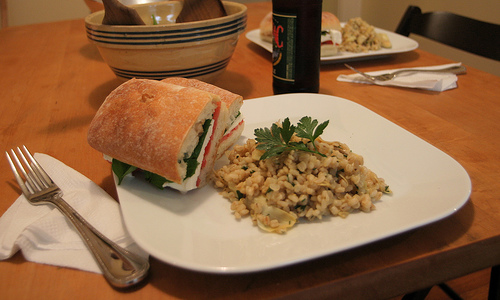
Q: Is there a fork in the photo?
A: Yes, there is a fork.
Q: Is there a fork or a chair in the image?
A: Yes, there is a fork.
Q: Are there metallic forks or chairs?
A: Yes, there is a metal fork.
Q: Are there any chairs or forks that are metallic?
A: Yes, the fork is metallic.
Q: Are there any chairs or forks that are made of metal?
A: Yes, the fork is made of metal.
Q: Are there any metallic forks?
A: Yes, there is a metal fork.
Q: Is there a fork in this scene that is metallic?
A: Yes, there is a fork that is metallic.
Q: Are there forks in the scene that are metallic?
A: Yes, there is a fork that is metallic.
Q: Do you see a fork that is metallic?
A: Yes, there is a fork that is metallic.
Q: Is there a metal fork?
A: Yes, there is a fork that is made of metal.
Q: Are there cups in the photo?
A: No, there are no cups.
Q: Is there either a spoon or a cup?
A: No, there are no cups or spoons.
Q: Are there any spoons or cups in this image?
A: No, there are no cups or spoons.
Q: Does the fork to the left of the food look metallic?
A: Yes, the fork is metallic.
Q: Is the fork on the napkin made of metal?
A: Yes, the fork is made of metal.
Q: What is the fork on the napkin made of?
A: The fork is made of metal.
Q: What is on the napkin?
A: The fork is on the napkin.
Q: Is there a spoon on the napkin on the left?
A: No, there is a fork on the napkin.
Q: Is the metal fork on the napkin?
A: Yes, the fork is on the napkin.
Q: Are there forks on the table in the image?
A: Yes, there is a fork on the table.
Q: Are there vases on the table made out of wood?
A: No, there is a fork on the table.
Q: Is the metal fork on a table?
A: Yes, the fork is on a table.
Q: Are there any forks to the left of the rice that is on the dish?
A: Yes, there is a fork to the left of the rice.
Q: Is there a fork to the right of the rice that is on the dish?
A: No, the fork is to the left of the rice.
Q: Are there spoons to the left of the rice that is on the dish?
A: No, there is a fork to the left of the rice.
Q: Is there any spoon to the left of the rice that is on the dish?
A: No, there is a fork to the left of the rice.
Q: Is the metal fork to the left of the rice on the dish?
A: Yes, the fork is to the left of the rice.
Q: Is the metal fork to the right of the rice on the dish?
A: No, the fork is to the left of the rice.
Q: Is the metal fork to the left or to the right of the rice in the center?
A: The fork is to the left of the rice.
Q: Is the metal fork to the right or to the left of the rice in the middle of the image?
A: The fork is to the left of the rice.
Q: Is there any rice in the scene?
A: Yes, there is rice.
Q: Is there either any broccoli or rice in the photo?
A: Yes, there is rice.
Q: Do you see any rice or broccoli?
A: Yes, there is rice.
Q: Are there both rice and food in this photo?
A: Yes, there are both rice and food.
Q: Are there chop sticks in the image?
A: No, there are no chop sticks.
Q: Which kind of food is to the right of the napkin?
A: The food is rice.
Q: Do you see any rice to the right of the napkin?
A: Yes, there is rice to the right of the napkin.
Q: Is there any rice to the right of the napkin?
A: Yes, there is rice to the right of the napkin.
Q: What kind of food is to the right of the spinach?
A: The food is rice.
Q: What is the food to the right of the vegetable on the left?
A: The food is rice.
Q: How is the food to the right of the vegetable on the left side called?
A: The food is rice.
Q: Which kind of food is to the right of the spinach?
A: The food is rice.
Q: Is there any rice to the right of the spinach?
A: Yes, there is rice to the right of the spinach.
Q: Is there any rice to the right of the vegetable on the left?
A: Yes, there is rice to the right of the spinach.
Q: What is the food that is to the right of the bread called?
A: The food is rice.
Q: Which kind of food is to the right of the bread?
A: The food is rice.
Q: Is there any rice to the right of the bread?
A: Yes, there is rice to the right of the bread.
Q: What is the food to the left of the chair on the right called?
A: The food is rice.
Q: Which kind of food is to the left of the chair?
A: The food is rice.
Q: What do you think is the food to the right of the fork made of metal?
A: The food is rice.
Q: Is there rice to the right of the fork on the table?
A: Yes, there is rice to the right of the fork.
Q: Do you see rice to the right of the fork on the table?
A: Yes, there is rice to the right of the fork.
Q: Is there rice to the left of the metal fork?
A: No, the rice is to the right of the fork.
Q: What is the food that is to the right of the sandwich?
A: The food is rice.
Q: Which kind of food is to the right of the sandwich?
A: The food is rice.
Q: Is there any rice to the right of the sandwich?
A: Yes, there is rice to the right of the sandwich.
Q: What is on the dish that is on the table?
A: The rice is on the dish.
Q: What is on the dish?
A: The rice is on the dish.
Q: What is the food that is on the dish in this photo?
A: The food is rice.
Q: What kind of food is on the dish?
A: The food is rice.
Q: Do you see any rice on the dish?
A: Yes, there is rice on the dish.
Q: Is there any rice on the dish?
A: Yes, there is rice on the dish.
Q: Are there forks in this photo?
A: Yes, there is a fork.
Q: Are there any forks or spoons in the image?
A: Yes, there is a fork.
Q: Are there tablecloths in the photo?
A: No, there are no tablecloths.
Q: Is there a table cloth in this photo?
A: No, there are no tablecloths.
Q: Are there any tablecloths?
A: No, there are no tablecloths.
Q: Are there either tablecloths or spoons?
A: No, there are no tablecloths or spoons.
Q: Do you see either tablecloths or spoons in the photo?
A: No, there are no tablecloths or spoons.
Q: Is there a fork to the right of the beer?
A: Yes, there is a fork to the right of the beer.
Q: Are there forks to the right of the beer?
A: Yes, there is a fork to the right of the beer.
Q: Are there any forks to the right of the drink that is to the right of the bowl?
A: Yes, there is a fork to the right of the beer.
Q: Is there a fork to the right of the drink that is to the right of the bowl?
A: Yes, there is a fork to the right of the beer.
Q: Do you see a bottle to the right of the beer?
A: No, there is a fork to the right of the beer.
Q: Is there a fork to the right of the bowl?
A: Yes, there is a fork to the right of the bowl.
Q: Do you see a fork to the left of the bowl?
A: No, the fork is to the right of the bowl.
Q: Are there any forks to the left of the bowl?
A: No, the fork is to the right of the bowl.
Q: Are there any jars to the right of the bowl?
A: No, there is a fork to the right of the bowl.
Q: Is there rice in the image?
A: Yes, there is rice.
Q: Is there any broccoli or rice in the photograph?
A: Yes, there is rice.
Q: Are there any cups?
A: No, there are no cups.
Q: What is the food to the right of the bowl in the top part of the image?
A: The food is rice.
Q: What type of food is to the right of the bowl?
A: The food is rice.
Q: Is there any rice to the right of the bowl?
A: Yes, there is rice to the right of the bowl.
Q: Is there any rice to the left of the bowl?
A: No, the rice is to the right of the bowl.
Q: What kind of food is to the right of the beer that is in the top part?
A: The food is rice.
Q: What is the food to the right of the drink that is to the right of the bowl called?
A: The food is rice.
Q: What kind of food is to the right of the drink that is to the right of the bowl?
A: The food is rice.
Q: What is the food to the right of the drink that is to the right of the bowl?
A: The food is rice.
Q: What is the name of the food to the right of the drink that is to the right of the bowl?
A: The food is rice.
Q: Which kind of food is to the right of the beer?
A: The food is rice.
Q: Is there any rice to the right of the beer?
A: Yes, there is rice to the right of the beer.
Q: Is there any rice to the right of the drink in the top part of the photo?
A: Yes, there is rice to the right of the beer.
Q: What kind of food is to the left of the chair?
A: The food is rice.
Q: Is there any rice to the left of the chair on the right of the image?
A: Yes, there is rice to the left of the chair.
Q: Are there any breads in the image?
A: Yes, there is a bread.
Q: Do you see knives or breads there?
A: Yes, there is a bread.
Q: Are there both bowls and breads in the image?
A: Yes, there are both a bread and a bowl.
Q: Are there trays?
A: No, there are no trays.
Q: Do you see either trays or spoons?
A: No, there are no trays or spoons.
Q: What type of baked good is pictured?
A: The baked good is a bread.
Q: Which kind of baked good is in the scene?
A: The baked good is a bread.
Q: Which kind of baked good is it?
A: The food is a bread.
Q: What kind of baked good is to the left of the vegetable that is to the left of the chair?
A: The food is a bread.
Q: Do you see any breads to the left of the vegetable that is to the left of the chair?
A: Yes, there is a bread to the left of the vegetable.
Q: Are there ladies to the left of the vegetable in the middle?
A: No, there is a bread to the left of the vegetable.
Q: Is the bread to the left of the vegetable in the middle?
A: Yes, the bread is to the left of the vegetable.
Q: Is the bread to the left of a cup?
A: No, the bread is to the left of the vegetable.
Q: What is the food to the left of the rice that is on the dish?
A: The food is a bread.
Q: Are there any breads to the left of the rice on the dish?
A: Yes, there is a bread to the left of the rice.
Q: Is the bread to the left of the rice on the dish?
A: Yes, the bread is to the left of the rice.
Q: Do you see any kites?
A: No, there are no kites.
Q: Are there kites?
A: No, there are no kites.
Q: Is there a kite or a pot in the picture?
A: No, there are no kites or pots.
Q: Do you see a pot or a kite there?
A: No, there are no kites or pots.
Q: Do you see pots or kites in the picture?
A: No, there are no kites or pots.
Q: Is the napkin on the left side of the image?
A: Yes, the napkin is on the left of the image.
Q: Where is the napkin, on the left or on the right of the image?
A: The napkin is on the left of the image.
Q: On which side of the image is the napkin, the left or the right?
A: The napkin is on the left of the image.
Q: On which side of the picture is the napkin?
A: The napkin is on the left of the image.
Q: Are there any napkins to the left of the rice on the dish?
A: Yes, there is a napkin to the left of the rice.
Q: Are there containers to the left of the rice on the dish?
A: No, there is a napkin to the left of the rice.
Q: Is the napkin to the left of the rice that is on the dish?
A: Yes, the napkin is to the left of the rice.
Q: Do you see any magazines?
A: No, there are no magazines.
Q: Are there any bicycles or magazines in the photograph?
A: No, there are no magazines or bicycles.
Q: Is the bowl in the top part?
A: Yes, the bowl is in the top of the image.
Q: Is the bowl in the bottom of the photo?
A: No, the bowl is in the top of the image.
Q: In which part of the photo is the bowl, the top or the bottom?
A: The bowl is in the top of the image.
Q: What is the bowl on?
A: The bowl is on the table.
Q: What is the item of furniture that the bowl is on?
A: The piece of furniture is a table.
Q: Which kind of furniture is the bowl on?
A: The bowl is on the table.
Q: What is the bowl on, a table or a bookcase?
A: The bowl is on a table.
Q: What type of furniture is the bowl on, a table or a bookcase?
A: The bowl is on a table.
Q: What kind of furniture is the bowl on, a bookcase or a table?
A: The bowl is on a table.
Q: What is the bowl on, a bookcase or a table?
A: The bowl is on a table.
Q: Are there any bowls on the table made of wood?
A: Yes, there is a bowl on the table.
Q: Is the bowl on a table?
A: Yes, the bowl is on a table.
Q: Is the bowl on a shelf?
A: No, the bowl is on a table.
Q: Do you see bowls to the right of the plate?
A: No, the bowl is to the left of the plate.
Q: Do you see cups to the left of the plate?
A: No, there is a bowl to the left of the plate.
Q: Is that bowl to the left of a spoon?
A: No, the bowl is to the left of the plate.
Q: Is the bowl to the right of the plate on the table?
A: No, the bowl is to the left of the plate.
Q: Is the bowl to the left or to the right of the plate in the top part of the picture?
A: The bowl is to the left of the plate.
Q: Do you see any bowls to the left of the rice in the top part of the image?
A: Yes, there is a bowl to the left of the rice.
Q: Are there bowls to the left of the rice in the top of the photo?
A: Yes, there is a bowl to the left of the rice.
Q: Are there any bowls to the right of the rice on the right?
A: No, the bowl is to the left of the rice.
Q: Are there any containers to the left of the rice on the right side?
A: No, there is a bowl to the left of the rice.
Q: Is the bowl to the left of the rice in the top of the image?
A: Yes, the bowl is to the left of the rice.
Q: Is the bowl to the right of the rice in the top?
A: No, the bowl is to the left of the rice.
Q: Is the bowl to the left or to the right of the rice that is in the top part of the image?
A: The bowl is to the left of the rice.